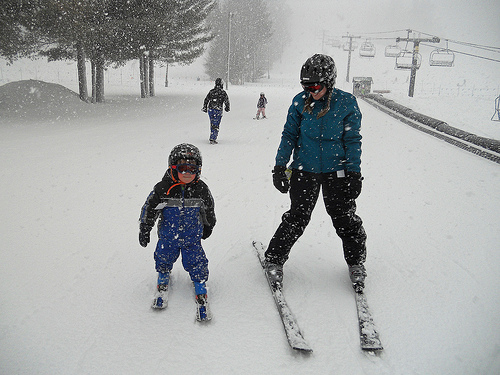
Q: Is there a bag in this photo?
A: No, there are no bags.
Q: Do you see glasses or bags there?
A: No, there are no bags or glasses.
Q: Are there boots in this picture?
A: Yes, there are boots.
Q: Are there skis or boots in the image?
A: Yes, there are boots.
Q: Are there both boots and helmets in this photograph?
A: Yes, there are both boots and a helmet.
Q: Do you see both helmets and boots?
A: Yes, there are both boots and a helmet.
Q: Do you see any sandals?
A: No, there are no sandals.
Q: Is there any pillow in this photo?
A: No, there are no pillows.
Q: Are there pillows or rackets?
A: No, there are no pillows or rackets.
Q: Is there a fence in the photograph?
A: No, there are no fences.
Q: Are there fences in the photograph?
A: No, there are no fences.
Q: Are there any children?
A: Yes, there is a child.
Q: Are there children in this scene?
A: Yes, there is a child.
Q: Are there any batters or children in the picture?
A: Yes, there is a child.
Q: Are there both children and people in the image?
A: Yes, there are both a child and people.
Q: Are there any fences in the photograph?
A: No, there are no fences.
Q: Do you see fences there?
A: No, there are no fences.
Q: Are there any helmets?
A: Yes, there is a helmet.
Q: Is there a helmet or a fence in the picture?
A: Yes, there is a helmet.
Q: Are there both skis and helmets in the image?
A: Yes, there are both a helmet and a ski.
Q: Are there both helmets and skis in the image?
A: Yes, there are both a helmet and a ski.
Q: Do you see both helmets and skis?
A: Yes, there are both a helmet and a ski.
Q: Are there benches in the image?
A: No, there are no benches.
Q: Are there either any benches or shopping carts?
A: No, there are no benches or shopping carts.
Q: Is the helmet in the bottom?
A: No, the helmet is in the top of the image.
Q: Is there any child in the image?
A: Yes, there is a child.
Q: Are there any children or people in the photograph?
A: Yes, there is a child.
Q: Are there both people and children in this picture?
A: Yes, there are both a child and a person.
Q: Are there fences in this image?
A: No, there are no fences.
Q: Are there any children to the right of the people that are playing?
A: Yes, there is a child to the right of the people.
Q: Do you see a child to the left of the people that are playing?
A: No, the child is to the right of the people.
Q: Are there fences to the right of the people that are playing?
A: No, there is a child to the right of the people.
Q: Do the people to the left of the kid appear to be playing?
A: Yes, the people are playing.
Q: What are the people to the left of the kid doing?
A: The people are playing.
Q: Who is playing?
A: The people are playing.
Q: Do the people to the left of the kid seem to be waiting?
A: No, the people are playing.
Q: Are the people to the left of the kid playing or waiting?
A: The people are playing.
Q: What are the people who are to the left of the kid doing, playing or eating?
A: The people are playing.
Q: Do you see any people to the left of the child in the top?
A: Yes, there are people to the left of the kid.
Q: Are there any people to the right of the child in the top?
A: No, the people are to the left of the child.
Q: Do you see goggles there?
A: Yes, there are goggles.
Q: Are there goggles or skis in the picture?
A: Yes, there are goggles.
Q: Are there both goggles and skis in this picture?
A: Yes, there are both goggles and a ski.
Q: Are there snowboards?
A: No, there are no snowboards.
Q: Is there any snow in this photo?
A: Yes, there is snow.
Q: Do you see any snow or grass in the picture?
A: Yes, there is snow.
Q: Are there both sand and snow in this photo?
A: No, there is snow but no sand.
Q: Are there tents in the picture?
A: No, there are no tents.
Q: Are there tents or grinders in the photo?
A: No, there are no tents or grinders.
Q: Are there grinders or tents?
A: No, there are no tents or grinders.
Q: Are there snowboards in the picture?
A: No, there are no snowboards.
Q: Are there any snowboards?
A: No, there are no snowboards.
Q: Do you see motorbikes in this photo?
A: No, there are no motorbikes.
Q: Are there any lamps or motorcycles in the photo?
A: No, there are no motorcycles or lamps.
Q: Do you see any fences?
A: No, there are no fences.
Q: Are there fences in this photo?
A: No, there are no fences.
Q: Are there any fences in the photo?
A: No, there are no fences.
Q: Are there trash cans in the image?
A: No, there are no trash cans.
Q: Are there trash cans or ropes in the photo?
A: No, there are no trash cans or ropes.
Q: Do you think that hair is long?
A: Yes, the hair is long.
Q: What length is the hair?
A: The hair is long.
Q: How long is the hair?
A: The hair is long.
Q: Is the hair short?
A: No, the hair is long.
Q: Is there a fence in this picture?
A: No, there are no fences.